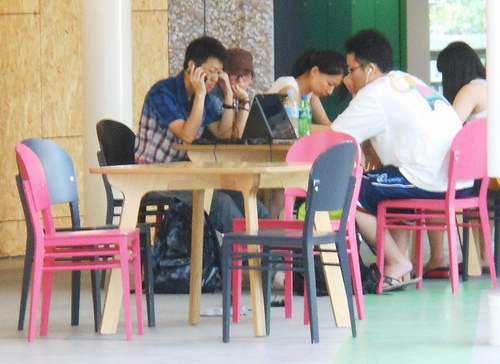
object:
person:
[328, 28, 474, 288]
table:
[87, 158, 359, 334]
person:
[131, 34, 288, 289]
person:
[414, 40, 500, 280]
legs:
[17, 205, 499, 343]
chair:
[219, 141, 358, 343]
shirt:
[329, 69, 475, 193]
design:
[387, 73, 451, 111]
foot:
[382, 263, 414, 289]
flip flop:
[383, 275, 421, 291]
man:
[134, 35, 271, 288]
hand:
[189, 63, 207, 92]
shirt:
[134, 72, 221, 165]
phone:
[187, 66, 208, 83]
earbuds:
[366, 68, 373, 86]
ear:
[367, 63, 375, 74]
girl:
[221, 47, 257, 141]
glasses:
[228, 73, 252, 80]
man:
[327, 27, 481, 291]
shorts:
[354, 165, 474, 217]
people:
[131, 30, 500, 291]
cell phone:
[186, 65, 207, 83]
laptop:
[192, 93, 297, 145]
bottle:
[298, 95, 313, 137]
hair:
[291, 49, 349, 79]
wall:
[0, 0, 170, 256]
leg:
[98, 204, 114, 290]